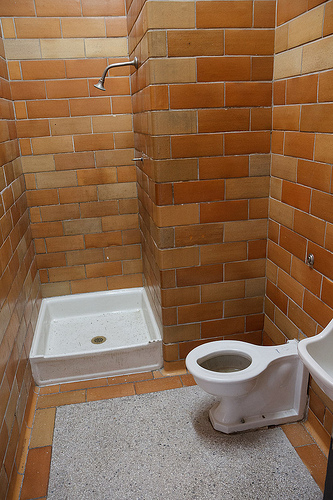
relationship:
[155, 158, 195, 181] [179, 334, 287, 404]
brick near toilet seat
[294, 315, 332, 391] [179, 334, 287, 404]
sink near toilet seat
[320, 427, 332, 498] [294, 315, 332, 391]
pole under sink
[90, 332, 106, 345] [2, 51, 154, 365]
drain inside shower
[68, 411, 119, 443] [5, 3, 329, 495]
tile inside bathroom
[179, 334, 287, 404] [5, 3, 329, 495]
toilet inside bathroom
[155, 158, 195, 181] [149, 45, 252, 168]
brick inside wall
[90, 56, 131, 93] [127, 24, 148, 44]
shower head attached to wall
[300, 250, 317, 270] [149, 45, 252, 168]
button alongside wall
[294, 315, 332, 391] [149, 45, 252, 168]
sink attached to wall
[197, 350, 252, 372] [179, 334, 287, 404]
hole in toilet seat